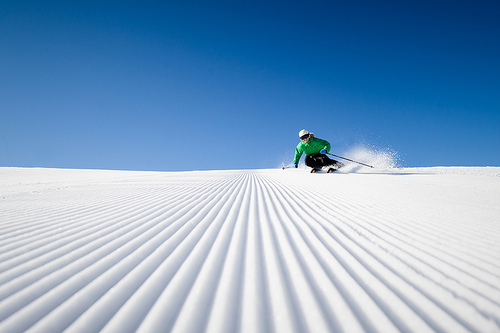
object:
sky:
[1, 0, 498, 172]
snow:
[345, 141, 433, 188]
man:
[294, 129, 346, 174]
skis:
[307, 165, 344, 173]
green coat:
[293, 135, 331, 165]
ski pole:
[323, 146, 377, 170]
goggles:
[297, 133, 312, 140]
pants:
[304, 149, 344, 174]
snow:
[0, 171, 131, 192]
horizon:
[3, 145, 483, 186]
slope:
[175, 171, 419, 317]